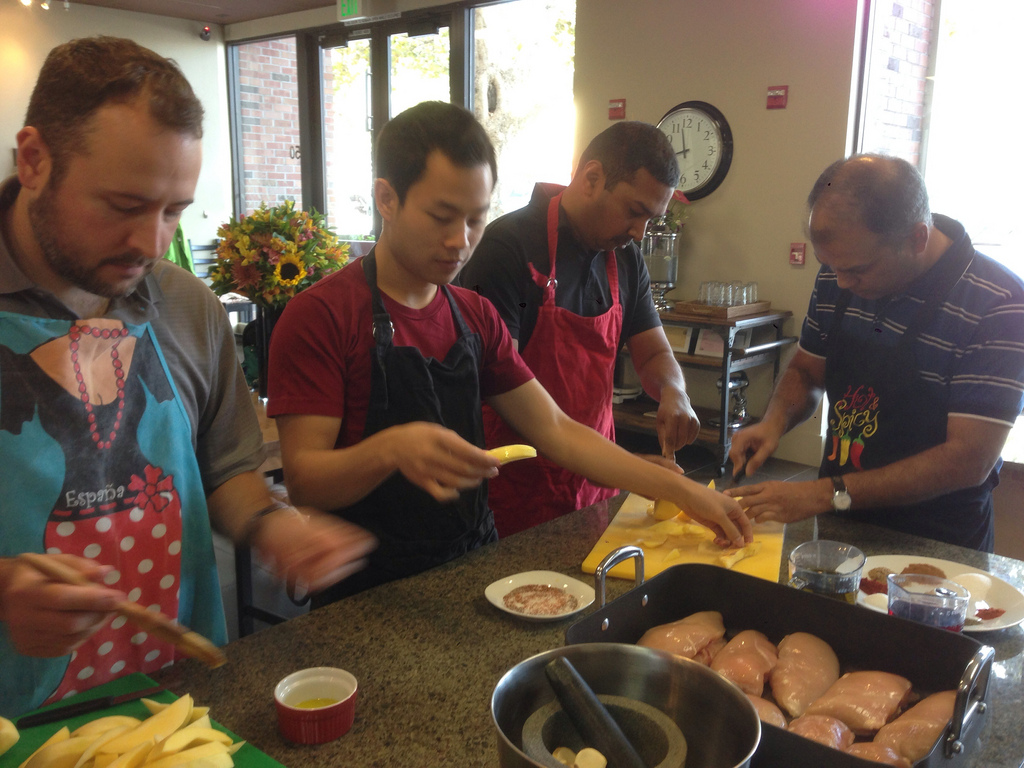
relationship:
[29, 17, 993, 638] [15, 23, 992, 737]
men in aprons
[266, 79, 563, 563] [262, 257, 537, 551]
man wears t-shirt